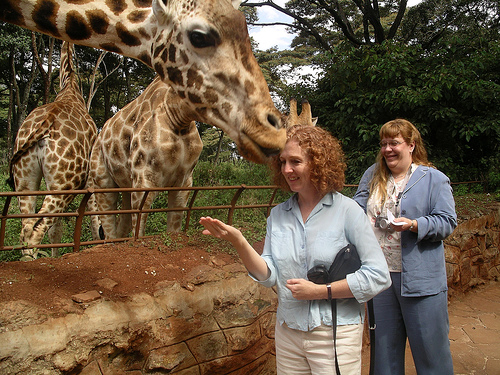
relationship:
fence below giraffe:
[4, 174, 360, 251] [23, 2, 280, 229]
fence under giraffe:
[4, 174, 360, 251] [23, 2, 280, 229]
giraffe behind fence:
[23, 2, 280, 229] [4, 174, 360, 251]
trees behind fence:
[4, 3, 497, 193] [4, 174, 360, 251]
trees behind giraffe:
[4, 3, 497, 193] [23, 2, 280, 229]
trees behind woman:
[4, 3, 497, 193] [212, 118, 387, 372]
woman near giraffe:
[212, 118, 387, 372] [23, 2, 280, 229]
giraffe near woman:
[23, 2, 280, 229] [212, 118, 387, 372]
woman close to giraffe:
[212, 118, 387, 372] [23, 2, 280, 229]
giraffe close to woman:
[23, 2, 280, 229] [212, 118, 387, 372]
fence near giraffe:
[4, 174, 360, 251] [23, 2, 280, 229]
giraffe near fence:
[23, 2, 280, 229] [4, 174, 360, 251]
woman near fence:
[212, 118, 387, 372] [4, 174, 360, 251]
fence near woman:
[4, 174, 360, 251] [212, 118, 387, 372]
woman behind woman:
[344, 113, 486, 343] [212, 118, 387, 372]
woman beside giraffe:
[212, 118, 387, 372] [23, 2, 280, 229]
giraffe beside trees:
[23, 2, 280, 229] [4, 3, 497, 193]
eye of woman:
[291, 155, 299, 163] [212, 118, 387, 372]